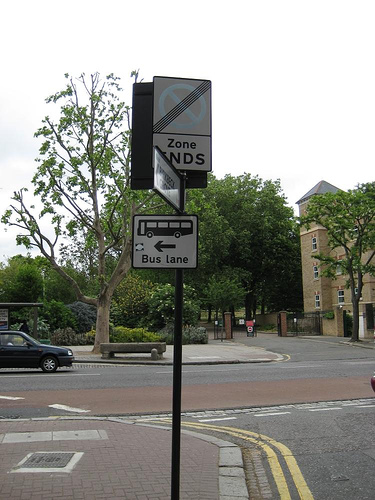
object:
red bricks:
[103, 457, 152, 483]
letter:
[194, 150, 205, 165]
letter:
[176, 256, 182, 263]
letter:
[173, 140, 181, 148]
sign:
[151, 75, 212, 171]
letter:
[148, 256, 154, 262]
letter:
[156, 255, 161, 263]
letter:
[168, 255, 176, 265]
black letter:
[195, 149, 207, 167]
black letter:
[165, 132, 177, 152]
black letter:
[140, 251, 148, 264]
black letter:
[162, 252, 170, 267]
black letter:
[182, 256, 188, 264]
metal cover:
[17, 448, 78, 474]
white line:
[48, 400, 91, 416]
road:
[0, 331, 375, 498]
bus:
[136, 218, 193, 239]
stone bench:
[100, 341, 166, 361]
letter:
[168, 151, 181, 167]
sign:
[132, 215, 198, 269]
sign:
[152, 145, 184, 211]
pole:
[170, 268, 183, 500]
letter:
[183, 153, 194, 165]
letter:
[182, 141, 190, 150]